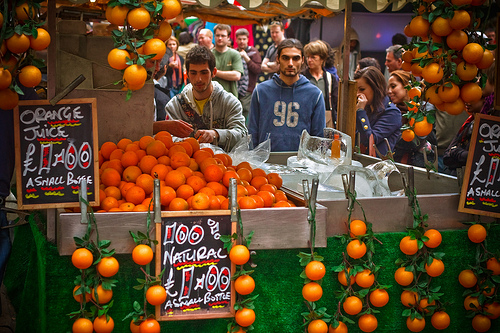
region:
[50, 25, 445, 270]
crowd of people with oranges.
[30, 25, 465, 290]
crowd of people with several oranges.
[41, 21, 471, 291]
crowd of people with multiple oranges.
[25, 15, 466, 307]
group of people with oranges.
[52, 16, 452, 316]
group of people with several oranges.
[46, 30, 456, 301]
group of people with piles of oranges.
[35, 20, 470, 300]
group of people with lots of oranges.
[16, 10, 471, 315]
group of people with some sweet oranges.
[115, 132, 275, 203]
a large amount of sweet oranges.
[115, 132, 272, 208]
a large pile of delicious oranges.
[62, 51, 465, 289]
Oranges ready sell customers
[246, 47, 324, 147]
Blue hoodie white 96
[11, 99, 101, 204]
Small bottle orange juice sign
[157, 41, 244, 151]
Preferential orange picking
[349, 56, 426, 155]
Women anxiously waiting turn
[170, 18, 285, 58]
Group patrons watching others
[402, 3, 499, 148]
More oranges hanging above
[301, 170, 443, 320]
Scissor hooks hold orange vines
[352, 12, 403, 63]
Entrance exit door distance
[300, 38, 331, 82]
Short haired person distant look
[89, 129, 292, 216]
orange is orange and round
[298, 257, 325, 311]
orange is orange and round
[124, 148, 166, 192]
orange is orange and round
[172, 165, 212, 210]
orange is orange and round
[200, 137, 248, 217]
orange is orange and round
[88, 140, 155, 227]
orange is orange and round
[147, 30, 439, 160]
The people are at an orange juice stand.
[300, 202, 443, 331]
Oranges hang from the stand.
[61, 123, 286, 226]
A large pile of oranges in on the stand.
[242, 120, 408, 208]
Equipment to squeeze the oranges is i the stand.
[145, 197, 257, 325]
A sign hangs from the stand.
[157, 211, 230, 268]
The sign reads 100% natural.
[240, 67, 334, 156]
The man is wearing a blue sweatshirt.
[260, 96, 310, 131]
The number 96 is on the man's sweatshirt.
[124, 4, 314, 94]
Several people are in the background.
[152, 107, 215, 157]
The man is giving money to the stand's operator.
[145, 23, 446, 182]
A bunch of people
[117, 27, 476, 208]
A group of people shopping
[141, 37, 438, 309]
People shopping at an orange stand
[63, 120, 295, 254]
A pile of oranges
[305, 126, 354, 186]
A bottle of orange juice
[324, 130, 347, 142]
An orange top on a bottle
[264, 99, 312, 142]
The number "96"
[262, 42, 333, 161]
The number "96" on a blue shirt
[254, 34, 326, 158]
A man in a blue shirt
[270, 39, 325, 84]
A man with a beard